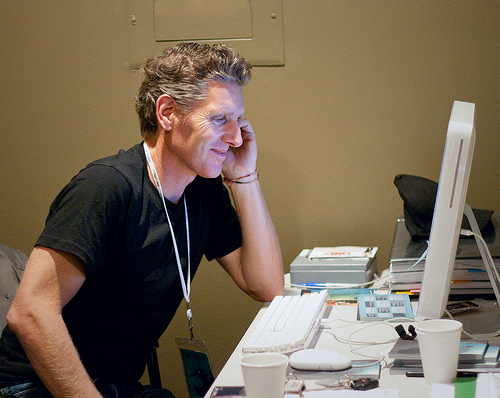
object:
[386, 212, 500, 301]
binder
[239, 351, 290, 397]
cup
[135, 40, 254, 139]
hair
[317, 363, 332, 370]
key set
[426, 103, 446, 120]
ground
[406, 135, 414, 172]
ground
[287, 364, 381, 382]
pad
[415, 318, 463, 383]
paper cup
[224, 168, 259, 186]
wrist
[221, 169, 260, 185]
bracelets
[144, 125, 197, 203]
neck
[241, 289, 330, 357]
keyboard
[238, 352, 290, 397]
plastic cup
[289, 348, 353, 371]
mouse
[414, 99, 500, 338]
computer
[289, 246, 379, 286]
books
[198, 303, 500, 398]
desk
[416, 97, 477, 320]
monitor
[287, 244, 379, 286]
box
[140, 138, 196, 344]
lanyard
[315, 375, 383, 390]
keys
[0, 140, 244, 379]
shirt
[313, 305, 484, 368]
cords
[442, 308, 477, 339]
cable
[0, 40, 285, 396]
man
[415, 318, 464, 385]
cup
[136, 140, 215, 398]
tag